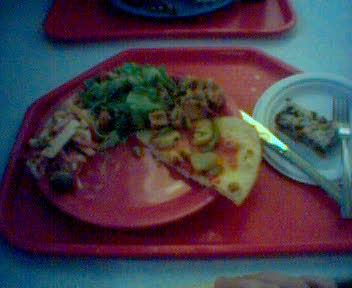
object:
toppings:
[32, 108, 94, 186]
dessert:
[273, 100, 341, 153]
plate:
[26, 68, 241, 226]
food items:
[94, 64, 160, 126]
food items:
[38, 119, 81, 161]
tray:
[0, 46, 352, 255]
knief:
[234, 107, 341, 207]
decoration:
[153, 119, 215, 171]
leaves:
[122, 84, 169, 111]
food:
[135, 117, 265, 208]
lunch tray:
[38, 2, 302, 42]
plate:
[104, 1, 238, 21]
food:
[47, 167, 76, 196]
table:
[10, 11, 330, 270]